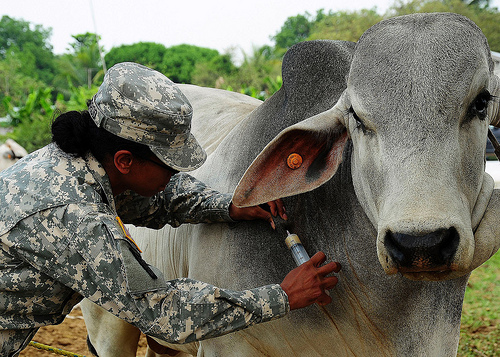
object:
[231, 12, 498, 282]
head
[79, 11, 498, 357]
cow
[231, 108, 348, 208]
ear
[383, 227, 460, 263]
nose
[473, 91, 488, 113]
eye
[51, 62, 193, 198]
head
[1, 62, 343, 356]
woman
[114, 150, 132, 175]
ear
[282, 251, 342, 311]
hand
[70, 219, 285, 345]
arm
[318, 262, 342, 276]
finger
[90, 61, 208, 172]
hat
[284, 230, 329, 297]
needle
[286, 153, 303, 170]
stud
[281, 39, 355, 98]
hump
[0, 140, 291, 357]
jacket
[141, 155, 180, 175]
glasses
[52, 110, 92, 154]
ponytail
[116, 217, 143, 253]
badge